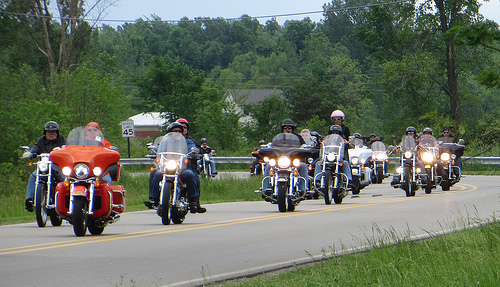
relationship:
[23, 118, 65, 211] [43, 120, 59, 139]
man has head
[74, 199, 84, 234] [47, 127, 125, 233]
wheel on motorcycle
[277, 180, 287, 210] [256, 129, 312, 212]
wheel on motorcycle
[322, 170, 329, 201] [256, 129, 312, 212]
wheel on motorcycle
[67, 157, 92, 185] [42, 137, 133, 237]
headlight on motocycle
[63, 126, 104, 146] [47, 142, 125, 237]
windshield on motorcycle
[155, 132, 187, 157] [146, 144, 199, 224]
windshield on motorcycle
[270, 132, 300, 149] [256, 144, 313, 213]
windshield on motorcycle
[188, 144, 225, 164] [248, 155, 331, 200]
mirror on motorcycle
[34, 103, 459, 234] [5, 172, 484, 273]
motorcycles on road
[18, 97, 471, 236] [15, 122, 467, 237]
people on motorcycles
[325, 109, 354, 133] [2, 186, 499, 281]
people on street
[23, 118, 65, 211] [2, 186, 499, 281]
man on street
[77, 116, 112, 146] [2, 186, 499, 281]
people on street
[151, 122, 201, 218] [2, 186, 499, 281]
people on street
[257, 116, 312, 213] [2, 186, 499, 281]
people on street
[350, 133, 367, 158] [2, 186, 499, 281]
people on street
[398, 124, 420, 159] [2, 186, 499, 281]
people on street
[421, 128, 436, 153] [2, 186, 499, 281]
people on street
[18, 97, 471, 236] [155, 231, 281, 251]
people on road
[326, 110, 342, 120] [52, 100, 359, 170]
helmet on people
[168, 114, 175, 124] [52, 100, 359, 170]
helmet on people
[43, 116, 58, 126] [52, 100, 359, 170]
helmet on people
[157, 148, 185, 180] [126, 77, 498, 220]
headlights on motorcycles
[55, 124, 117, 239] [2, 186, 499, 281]
motorcycle driving down street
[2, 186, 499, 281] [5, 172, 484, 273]
street on road